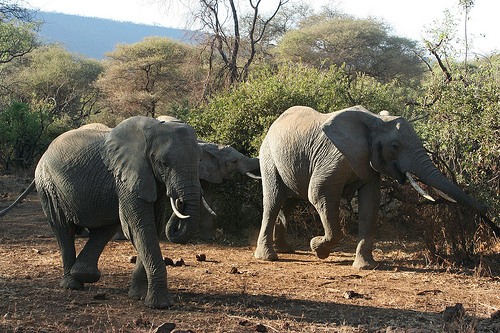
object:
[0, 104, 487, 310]
three elephants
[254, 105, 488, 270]
elephant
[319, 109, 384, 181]
ear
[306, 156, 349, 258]
front right foot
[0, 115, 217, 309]
elephant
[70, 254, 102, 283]
back left foot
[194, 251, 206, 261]
elephant dung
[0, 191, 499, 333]
ground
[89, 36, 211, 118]
trees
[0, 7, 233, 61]
mountain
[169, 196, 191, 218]
tusks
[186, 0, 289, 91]
tree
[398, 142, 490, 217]
trunk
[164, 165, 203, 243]
trunk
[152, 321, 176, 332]
rocks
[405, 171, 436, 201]
tusks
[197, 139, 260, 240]
elephant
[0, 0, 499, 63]
sky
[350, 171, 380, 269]
front legs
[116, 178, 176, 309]
front legs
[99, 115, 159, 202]
ear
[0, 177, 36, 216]
tail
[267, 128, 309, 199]
stomach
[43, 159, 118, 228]
stomach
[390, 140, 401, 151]
eye